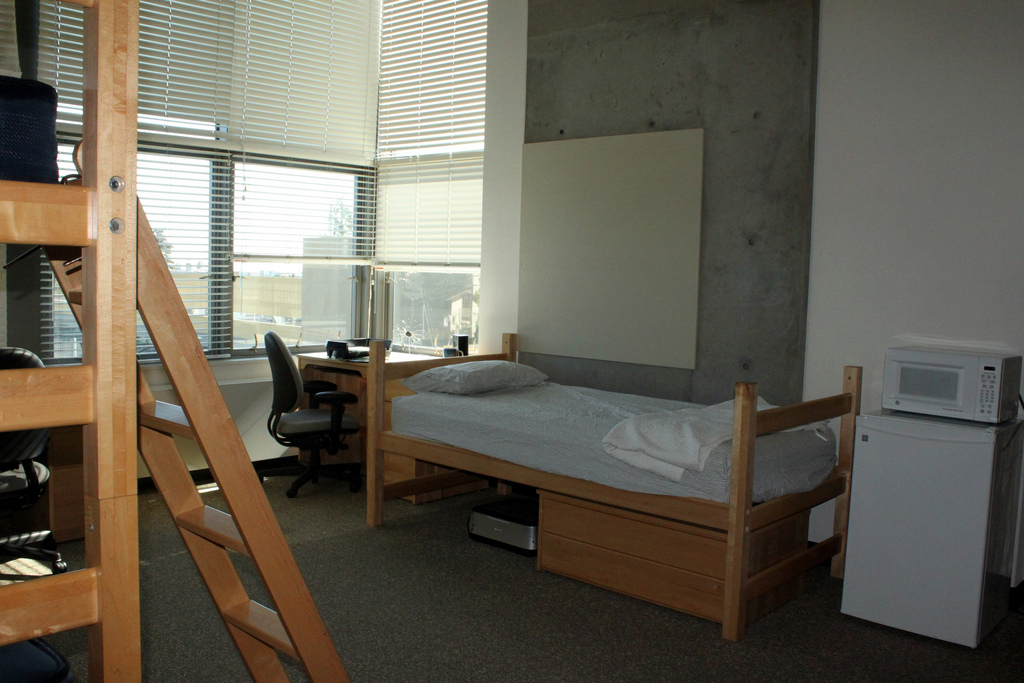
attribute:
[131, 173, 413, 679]
stairs — small 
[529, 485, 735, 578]
drawer — wooden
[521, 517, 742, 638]
drawer — wooden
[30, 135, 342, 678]
ladder — wooden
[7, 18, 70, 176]
bunk — top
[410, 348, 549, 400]
pillow — white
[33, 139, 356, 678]
staircase — short, wooden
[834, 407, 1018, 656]
fridge — white, mini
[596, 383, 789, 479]
sheet — folded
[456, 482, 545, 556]
object — black, silver, box-like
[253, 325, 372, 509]
chair — gray, black, office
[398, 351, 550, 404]
pillow — white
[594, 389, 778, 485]
blanket — white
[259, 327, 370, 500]
chair — black, grey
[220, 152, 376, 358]
window — small, black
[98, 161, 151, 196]
bolt — metal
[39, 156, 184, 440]
bed — metal